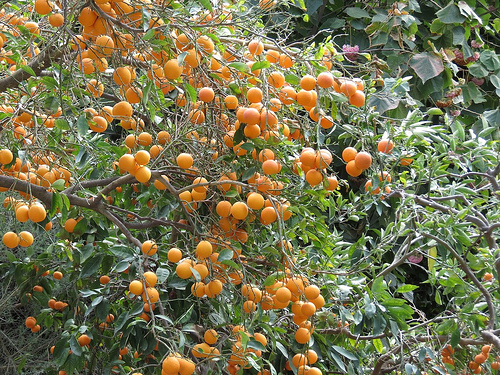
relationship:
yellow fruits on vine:
[118, 140, 158, 180] [141, 122, 188, 207]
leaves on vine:
[325, 216, 467, 343] [141, 122, 188, 207]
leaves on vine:
[340, 290, 395, 334] [275, 320, 383, 343]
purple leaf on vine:
[339, 42, 361, 62] [300, 42, 357, 61]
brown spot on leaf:
[55, 203, 61, 214] [46, 187, 62, 219]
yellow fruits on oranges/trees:
[0, 0, 412, 375] [1, 0, 499, 375]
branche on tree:
[4, 177, 120, 207] [24, 5, 410, 353]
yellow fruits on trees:
[0, 0, 412, 375] [237, 50, 432, 290]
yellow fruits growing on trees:
[0, 0, 412, 375] [237, 50, 432, 290]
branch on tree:
[432, 153, 497, 188] [42, 29, 467, 355]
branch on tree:
[389, 172, 498, 239] [42, 29, 467, 355]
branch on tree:
[401, 212, 497, 336] [42, 29, 467, 355]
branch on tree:
[356, 227, 426, 282] [42, 29, 467, 355]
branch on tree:
[334, 187, 412, 236] [42, 29, 467, 355]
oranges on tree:
[177, 71, 330, 266] [50, 38, 449, 368]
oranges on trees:
[3, 9, 327, 366] [20, 16, 469, 352]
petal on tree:
[408, 248, 423, 265] [241, 0, 498, 327]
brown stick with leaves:
[418, 230, 498, 344] [321, 99, 467, 230]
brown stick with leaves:
[1, 174, 177, 207] [107, 212, 187, 272]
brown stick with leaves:
[0, 42, 64, 91] [58, 161, 274, 203]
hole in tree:
[387, 252, 450, 329] [7, 49, 493, 370]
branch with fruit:
[111, 138, 338, 229] [352, 151, 369, 166]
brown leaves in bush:
[386, 3, 408, 18] [0, 0, 500, 374]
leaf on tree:
[184, 342, 226, 361] [83, 31, 446, 349]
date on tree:
[191, 360, 201, 371] [83, 31, 446, 349]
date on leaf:
[191, 360, 201, 371] [184, 342, 226, 361]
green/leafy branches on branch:
[385, 169, 499, 371] [356, 227, 426, 282]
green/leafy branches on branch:
[0, 160, 269, 298] [356, 227, 426, 282]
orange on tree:
[210, 76, 281, 154] [93, 49, 423, 325]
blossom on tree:
[338, 42, 360, 60] [252, 0, 499, 210]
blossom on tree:
[446, 41, 477, 63] [252, 0, 499, 210]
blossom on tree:
[448, 101, 463, 118] [252, 0, 499, 210]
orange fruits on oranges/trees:
[89, 12, 361, 210] [1, 0, 499, 375]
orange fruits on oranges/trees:
[152, 243, 312, 373] [1, 0, 499, 375]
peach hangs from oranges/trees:
[243, 107, 260, 124] [1, 0, 499, 375]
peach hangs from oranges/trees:
[134, 149, 150, 163] [1, 0, 499, 375]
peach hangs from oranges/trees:
[27, 204, 47, 223] [1, 0, 499, 375]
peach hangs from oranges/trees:
[231, 201, 248, 219] [1, 0, 499, 375]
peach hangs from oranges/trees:
[167, 247, 182, 263] [1, 0, 499, 375]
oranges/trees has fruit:
[1, 0, 499, 375] [2, 0, 497, 372]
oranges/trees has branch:
[1, 0, 499, 375] [2, 214, 64, 369]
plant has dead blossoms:
[355, 1, 497, 121] [433, 86, 468, 116]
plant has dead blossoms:
[355, 1, 497, 121] [455, 47, 482, 64]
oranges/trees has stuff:
[1, 0, 499, 375] [56, 25, 391, 325]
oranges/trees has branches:
[1, 0, 499, 375] [151, 59, 386, 300]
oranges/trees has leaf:
[1, 0, 499, 375] [343, 232, 372, 260]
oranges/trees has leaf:
[1, 0, 499, 375] [390, 276, 419, 297]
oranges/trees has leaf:
[1, 0, 499, 375] [384, 302, 416, 321]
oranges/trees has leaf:
[1, 0, 499, 375] [330, 282, 361, 309]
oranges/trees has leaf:
[1, 0, 499, 375] [295, 227, 317, 248]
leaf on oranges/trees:
[403, 52, 443, 84] [1, 0, 499, 375]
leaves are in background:
[391, 151, 495, 356] [295, 14, 496, 368]